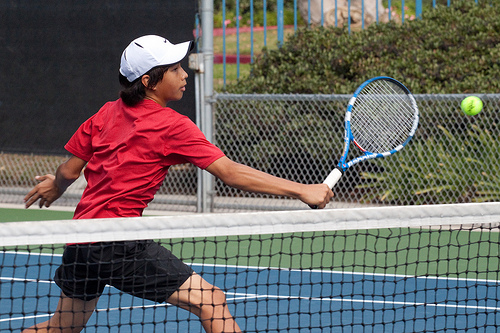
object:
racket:
[318, 75, 420, 198]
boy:
[23, 34, 335, 333]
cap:
[118, 34, 190, 81]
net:
[0, 202, 497, 333]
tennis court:
[0, 204, 500, 333]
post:
[222, 1, 224, 91]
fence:
[207, 94, 500, 211]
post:
[249, 1, 253, 71]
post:
[277, 0, 286, 46]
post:
[306, 0, 310, 26]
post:
[334, 1, 341, 31]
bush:
[209, 3, 500, 203]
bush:
[397, 134, 498, 206]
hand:
[23, 173, 62, 209]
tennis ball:
[458, 93, 483, 118]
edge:
[0, 202, 499, 248]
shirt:
[63, 98, 227, 219]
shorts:
[54, 238, 199, 304]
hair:
[118, 65, 166, 107]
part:
[0, 255, 499, 332]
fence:
[213, 0, 500, 95]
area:
[0, 201, 499, 281]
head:
[119, 34, 189, 102]